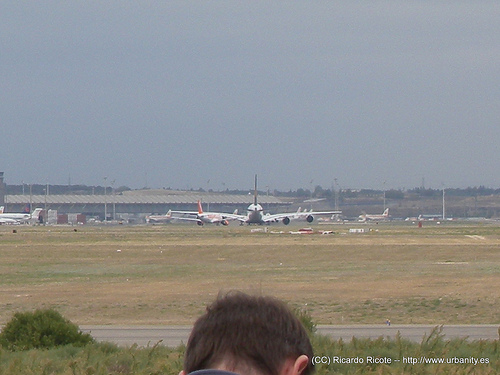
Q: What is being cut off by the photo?
A: A man's head.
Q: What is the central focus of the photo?
A: A plane.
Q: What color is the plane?
A: White.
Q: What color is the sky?
A: Gray.